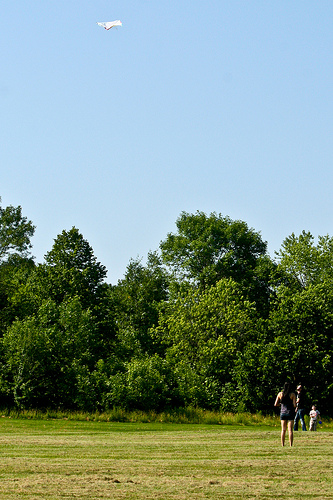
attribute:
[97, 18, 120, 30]
kite — white, flying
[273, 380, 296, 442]
woman — standing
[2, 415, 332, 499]
grass — green, tall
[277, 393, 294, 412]
shirt — black, gray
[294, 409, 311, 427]
jeans — blue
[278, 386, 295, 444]
person — standing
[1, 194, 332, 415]
tree — green, large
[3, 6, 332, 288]
sky — blue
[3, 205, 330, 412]
leaves — green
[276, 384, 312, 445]
people — standing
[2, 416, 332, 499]
field — open, grassy, large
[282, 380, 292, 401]
hair — long, black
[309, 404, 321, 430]
man — looking